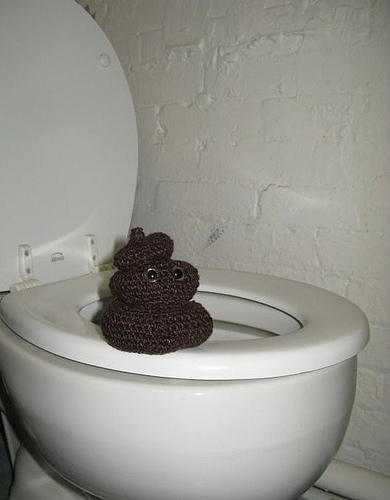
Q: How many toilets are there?
A: 1.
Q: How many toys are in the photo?
A: 1.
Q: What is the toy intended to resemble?
A: Feces.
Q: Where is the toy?
A: On the seat.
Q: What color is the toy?
A: Brown.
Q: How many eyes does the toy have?
A: 2.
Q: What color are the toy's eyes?
A: Black.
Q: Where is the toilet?
A: By the wall.